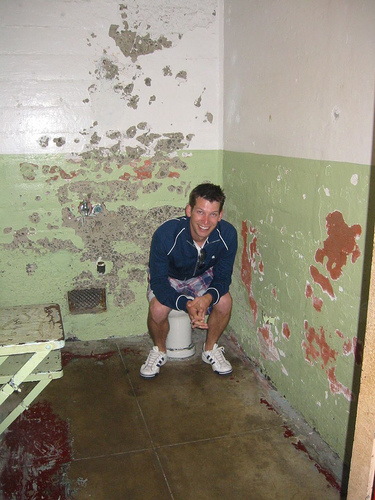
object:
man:
[138, 180, 238, 380]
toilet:
[154, 299, 196, 360]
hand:
[186, 300, 209, 331]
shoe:
[138, 342, 168, 379]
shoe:
[201, 340, 234, 376]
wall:
[1, 3, 374, 486]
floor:
[0, 326, 349, 500]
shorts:
[146, 265, 215, 317]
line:
[114, 338, 154, 448]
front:
[139, 362, 155, 378]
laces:
[146, 350, 161, 367]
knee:
[151, 299, 169, 325]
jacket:
[149, 218, 238, 309]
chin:
[196, 231, 211, 238]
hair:
[189, 183, 226, 215]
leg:
[200, 293, 233, 352]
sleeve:
[145, 243, 194, 314]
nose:
[201, 214, 209, 225]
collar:
[184, 219, 196, 249]